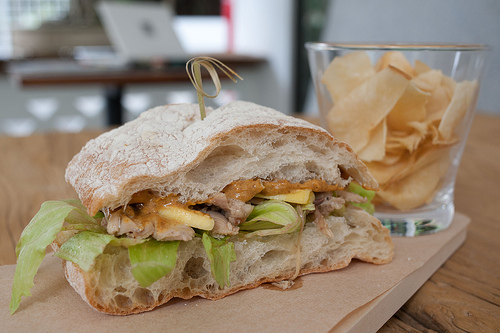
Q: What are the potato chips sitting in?
A: Glass.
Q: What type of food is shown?
A: Sandwich and chips.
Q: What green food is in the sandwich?
A: Lettuce.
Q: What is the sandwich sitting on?
A: Napkin.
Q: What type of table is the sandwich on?
A: Wood table.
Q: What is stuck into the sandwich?
A: Toothpick.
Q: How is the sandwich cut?
A: In half.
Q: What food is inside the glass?
A: Chips.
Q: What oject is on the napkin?
A: A sandwich.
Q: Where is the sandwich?
A: Beside the cup.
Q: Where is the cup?
A: On the napkin.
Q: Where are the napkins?
A: On the table.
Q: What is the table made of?
A: Wood.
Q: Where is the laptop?
A: On the far table.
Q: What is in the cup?
A: Chips.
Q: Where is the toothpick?
A: In the sandwich.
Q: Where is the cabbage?
A: In the sandwich.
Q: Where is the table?
A: Beneath the food.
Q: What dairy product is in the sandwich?
A: Cheese.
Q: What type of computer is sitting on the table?
A: Laptop.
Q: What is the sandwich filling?
A: Lettuce, meat, tomato and cheese.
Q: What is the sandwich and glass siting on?
A: Paper.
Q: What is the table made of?
A: Wood.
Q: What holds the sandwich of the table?
A: A wooden board.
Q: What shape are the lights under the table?
A: Heart shaped.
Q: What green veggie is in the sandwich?
A: Lettuce.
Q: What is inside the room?
A: A wooden table.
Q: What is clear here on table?
A: A small glass.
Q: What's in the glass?
A: Some chips.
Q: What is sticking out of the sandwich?
A: Lettuce.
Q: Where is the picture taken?
A: At a restaurant.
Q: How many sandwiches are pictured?
A: One.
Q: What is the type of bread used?
A: Ciabatta.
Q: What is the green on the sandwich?
A: Lettuce.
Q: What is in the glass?
A: Chips.